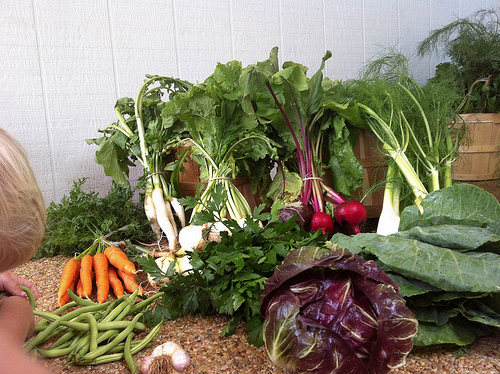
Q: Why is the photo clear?
A: Its during the day.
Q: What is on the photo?
A: Vegetables.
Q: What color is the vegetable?
A: Green.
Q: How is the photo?
A: Clear.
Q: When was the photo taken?
A: Daytime.